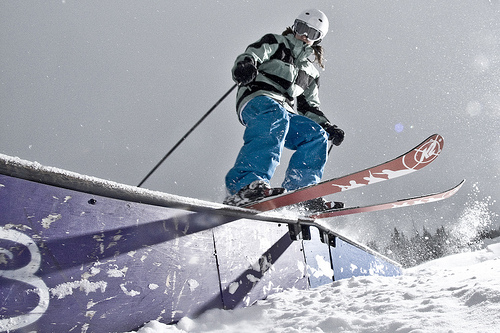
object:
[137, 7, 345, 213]
girl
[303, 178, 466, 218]
skiboard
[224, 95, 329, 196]
pants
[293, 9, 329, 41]
helmet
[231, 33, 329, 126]
jacket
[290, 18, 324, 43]
goggles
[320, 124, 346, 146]
gloves